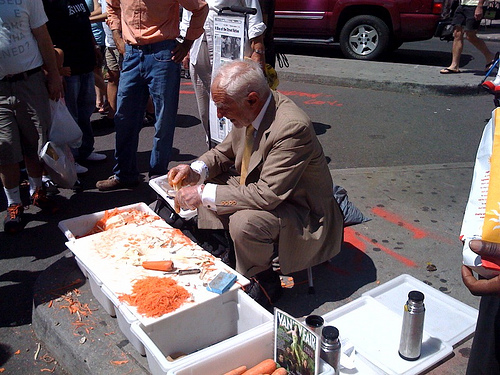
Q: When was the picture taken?
A: During daylight hours.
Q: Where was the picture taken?
A: On a city street.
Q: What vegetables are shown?
A: Carrots.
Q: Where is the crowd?
A: Gathered around the man.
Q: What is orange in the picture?
A: Carrots.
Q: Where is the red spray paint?
A: On the street.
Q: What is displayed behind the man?
A: Newspaper articles.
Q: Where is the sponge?
A: On the cutting board.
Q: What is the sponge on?
A: A cutting board.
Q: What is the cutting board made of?
A: Plastic.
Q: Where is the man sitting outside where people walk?
A: Sidewalk.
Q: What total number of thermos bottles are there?
A: 3.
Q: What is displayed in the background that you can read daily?
A: Newspaper.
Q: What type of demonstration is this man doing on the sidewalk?
A: Peeling carrots.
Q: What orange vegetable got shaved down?
A: Carrot.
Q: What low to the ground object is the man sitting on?
A: Stool.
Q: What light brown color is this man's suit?
A: Tan.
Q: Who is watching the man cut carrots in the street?
A: Bystanders.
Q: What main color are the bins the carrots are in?
A: White.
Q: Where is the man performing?
A: Sidewalk.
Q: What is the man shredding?
A: Carrots.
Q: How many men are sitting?
A: 1.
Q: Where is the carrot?
A: On a board.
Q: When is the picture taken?
A: Daytime.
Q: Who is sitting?
A: A man.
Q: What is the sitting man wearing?
A: A suit.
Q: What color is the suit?
A: Brown.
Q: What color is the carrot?
A: Orange.